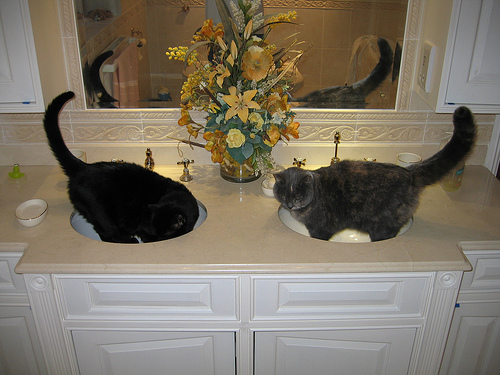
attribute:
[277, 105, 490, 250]
cat — grey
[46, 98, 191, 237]
cat — black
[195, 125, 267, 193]
vase — glass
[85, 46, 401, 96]
tails — reflecting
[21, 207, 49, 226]
bowl — white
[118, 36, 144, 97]
towel — pink, reflecting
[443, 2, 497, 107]
cabinet — white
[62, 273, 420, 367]
cabinet — white